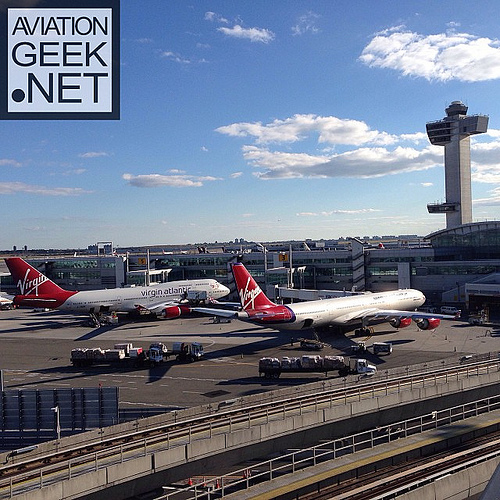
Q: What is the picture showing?
A: An airport.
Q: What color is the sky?
A: Blue.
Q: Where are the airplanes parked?
A: The ramp.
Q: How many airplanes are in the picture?
A: Two.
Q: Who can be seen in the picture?
A: No one.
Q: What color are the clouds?
A: White.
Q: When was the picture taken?
A: During the day.